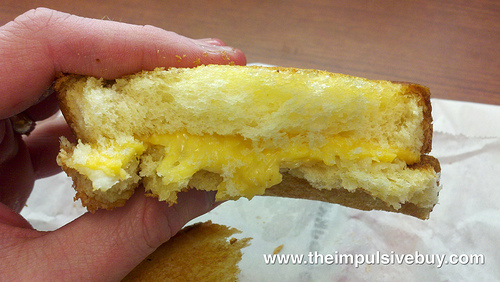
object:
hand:
[0, 3, 249, 281]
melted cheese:
[65, 126, 423, 201]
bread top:
[52, 65, 434, 136]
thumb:
[0, 185, 239, 282]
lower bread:
[62, 165, 449, 220]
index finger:
[0, 7, 248, 87]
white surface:
[19, 62, 500, 282]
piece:
[71, 78, 133, 193]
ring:
[3, 107, 39, 136]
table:
[0, 0, 499, 107]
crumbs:
[172, 52, 188, 59]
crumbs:
[267, 243, 287, 259]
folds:
[0, 203, 59, 242]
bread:
[122, 220, 253, 282]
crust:
[403, 81, 443, 221]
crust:
[50, 73, 95, 212]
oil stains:
[237, 200, 325, 238]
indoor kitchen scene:
[1, 0, 498, 280]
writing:
[259, 248, 490, 269]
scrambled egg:
[63, 131, 284, 199]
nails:
[189, 38, 237, 54]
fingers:
[0, 7, 247, 121]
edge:
[430, 91, 498, 144]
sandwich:
[54, 63, 448, 222]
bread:
[50, 64, 443, 220]